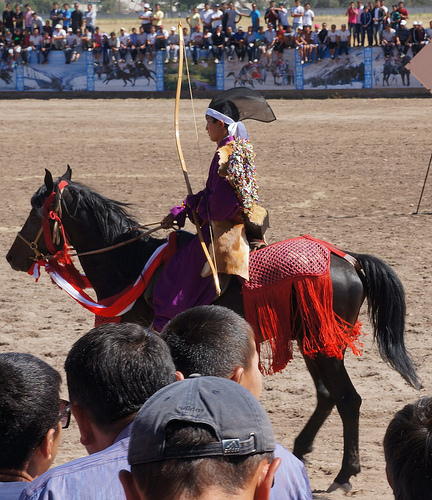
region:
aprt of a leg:
[295, 362, 341, 439]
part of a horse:
[294, 243, 330, 294]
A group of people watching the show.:
[9, 4, 173, 76]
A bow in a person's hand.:
[162, 9, 224, 261]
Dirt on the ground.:
[330, 111, 370, 145]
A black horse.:
[12, 150, 415, 438]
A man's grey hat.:
[113, 364, 285, 473]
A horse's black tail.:
[335, 227, 430, 333]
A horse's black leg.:
[299, 293, 376, 492]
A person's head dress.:
[195, 77, 285, 135]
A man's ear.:
[249, 456, 302, 499]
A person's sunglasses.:
[43, 383, 82, 439]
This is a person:
[113, 374, 215, 493]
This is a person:
[65, 322, 191, 492]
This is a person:
[0, 345, 83, 499]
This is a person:
[159, 298, 294, 422]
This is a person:
[138, 86, 274, 326]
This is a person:
[151, 3, 168, 33]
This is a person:
[137, 0, 154, 36]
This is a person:
[346, 0, 358, 39]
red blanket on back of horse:
[249, 241, 332, 347]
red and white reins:
[23, 243, 189, 316]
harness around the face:
[13, 182, 69, 275]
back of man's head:
[139, 378, 275, 486]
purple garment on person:
[164, 228, 242, 316]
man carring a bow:
[157, 28, 224, 283]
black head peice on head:
[214, 87, 271, 122]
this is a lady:
[168, 75, 271, 230]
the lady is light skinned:
[208, 124, 224, 133]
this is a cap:
[129, 377, 246, 450]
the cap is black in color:
[210, 380, 240, 419]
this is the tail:
[366, 259, 409, 326]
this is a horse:
[21, 163, 146, 329]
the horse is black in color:
[332, 264, 343, 286]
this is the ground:
[303, 124, 393, 206]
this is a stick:
[170, 37, 192, 212]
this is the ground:
[324, 132, 397, 178]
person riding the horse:
[142, 105, 262, 309]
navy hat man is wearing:
[134, 370, 272, 462]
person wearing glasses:
[2, 349, 79, 499]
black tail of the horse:
[358, 250, 420, 383]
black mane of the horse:
[65, 177, 147, 241]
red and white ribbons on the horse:
[38, 182, 169, 320]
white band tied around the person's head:
[202, 108, 248, 138]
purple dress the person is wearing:
[145, 153, 241, 309]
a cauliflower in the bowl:
[395, 17, 418, 35]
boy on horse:
[150, 98, 271, 328]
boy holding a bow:
[168, 95, 274, 306]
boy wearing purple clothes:
[152, 98, 271, 322]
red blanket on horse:
[239, 228, 361, 370]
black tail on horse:
[340, 244, 425, 397]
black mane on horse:
[63, 176, 147, 247]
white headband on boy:
[194, 103, 247, 137]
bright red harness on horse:
[29, 175, 174, 323]